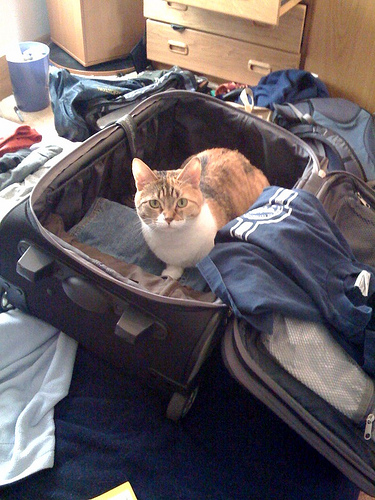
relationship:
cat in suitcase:
[131, 146, 271, 279] [4, 77, 374, 497]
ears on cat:
[122, 151, 221, 194] [93, 120, 294, 305]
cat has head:
[131, 146, 271, 279] [130, 155, 202, 231]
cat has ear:
[131, 146, 271, 279] [171, 157, 212, 190]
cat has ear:
[131, 146, 271, 279] [126, 153, 161, 189]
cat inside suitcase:
[131, 146, 271, 279] [79, 95, 276, 314]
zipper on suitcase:
[361, 409, 373, 436] [4, 77, 374, 497]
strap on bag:
[277, 112, 371, 182] [267, 88, 374, 185]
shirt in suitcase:
[195, 184, 375, 376] [4, 77, 374, 497]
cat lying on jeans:
[103, 158, 212, 282] [66, 194, 212, 292]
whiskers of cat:
[133, 210, 204, 236] [131, 137, 274, 273]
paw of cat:
[158, 262, 188, 280] [131, 146, 271, 279]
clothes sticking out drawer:
[162, 21, 190, 34] [135, 55, 273, 93]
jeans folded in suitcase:
[66, 194, 212, 292] [4, 77, 374, 497]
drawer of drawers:
[145, 18, 302, 90] [141, 0, 306, 86]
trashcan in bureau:
[3, 37, 67, 118] [0, 0, 375, 497]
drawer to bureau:
[145, 18, 299, 89] [141, 0, 306, 91]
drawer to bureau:
[142, 1, 307, 54] [141, 0, 306, 91]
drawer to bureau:
[165, 1, 300, 24] [141, 0, 306, 91]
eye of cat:
[172, 195, 191, 211] [131, 146, 271, 279]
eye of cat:
[148, 199, 162, 212] [131, 146, 271, 279]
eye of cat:
[148, 199, 159, 208] [131, 146, 271, 279]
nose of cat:
[160, 207, 175, 225] [127, 163, 260, 266]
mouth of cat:
[160, 222, 178, 232] [131, 146, 271, 279]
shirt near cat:
[177, 184, 373, 339] [131, 146, 271, 279]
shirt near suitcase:
[195, 184, 375, 376] [4, 77, 374, 497]